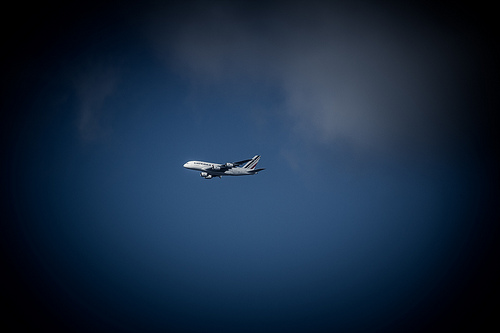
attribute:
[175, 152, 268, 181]
airplane — white 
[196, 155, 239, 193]
airplane engines — round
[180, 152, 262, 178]
plane — small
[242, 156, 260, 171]
stripes — dark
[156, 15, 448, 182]
cloud — white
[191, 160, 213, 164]
lateral windows — small 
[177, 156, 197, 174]
nose — white, rounded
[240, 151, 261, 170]
spoiler — rear